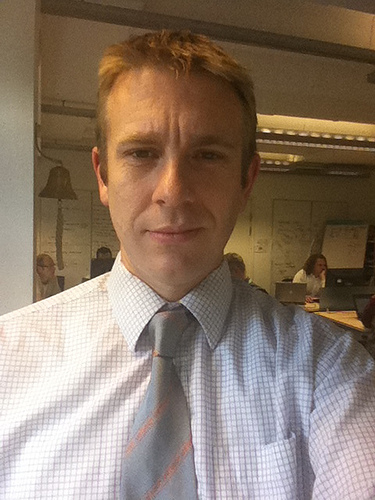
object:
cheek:
[108, 180, 143, 254]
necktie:
[119, 305, 198, 500]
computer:
[275, 283, 308, 305]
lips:
[149, 225, 202, 241]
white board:
[268, 199, 346, 298]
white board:
[39, 189, 120, 291]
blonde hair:
[95, 31, 257, 187]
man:
[34, 253, 62, 303]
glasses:
[38, 263, 55, 268]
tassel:
[55, 201, 65, 271]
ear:
[92, 147, 109, 206]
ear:
[241, 153, 261, 214]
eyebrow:
[191, 132, 235, 149]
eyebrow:
[116, 131, 162, 144]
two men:
[35, 247, 117, 303]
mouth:
[144, 227, 205, 243]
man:
[0, 33, 375, 500]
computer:
[90, 258, 116, 278]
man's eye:
[124, 147, 156, 160]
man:
[293, 254, 328, 303]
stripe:
[123, 382, 177, 452]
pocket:
[257, 427, 307, 498]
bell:
[37, 165, 77, 199]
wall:
[4, 3, 37, 311]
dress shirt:
[0, 252, 373, 499]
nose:
[152, 155, 196, 208]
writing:
[61, 222, 80, 226]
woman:
[292, 254, 330, 303]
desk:
[309, 309, 374, 342]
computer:
[319, 286, 357, 311]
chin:
[121, 236, 220, 284]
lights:
[261, 127, 271, 135]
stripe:
[140, 436, 191, 498]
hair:
[293, 253, 327, 280]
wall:
[31, 143, 373, 306]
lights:
[274, 128, 284, 135]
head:
[92, 30, 258, 285]